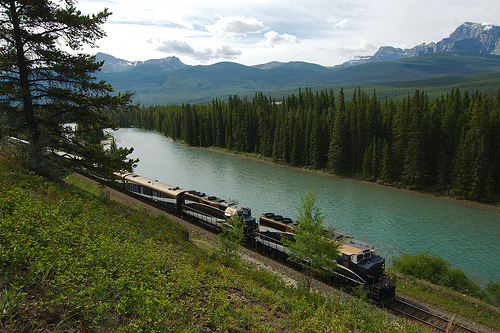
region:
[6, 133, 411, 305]
train running along a river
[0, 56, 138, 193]
pine trees overlooking a river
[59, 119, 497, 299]
light green river next to a train track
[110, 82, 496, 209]
pine trees lining the shore of a river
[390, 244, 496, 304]
green brush along the side of a river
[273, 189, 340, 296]
small tree near train tracks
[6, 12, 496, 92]
tall mountains against the sky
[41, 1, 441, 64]
bright sunlight shining off white clouds in blue sky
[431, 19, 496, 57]
rocky peak beneath blue sky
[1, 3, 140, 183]
tall pine tree above a train and a river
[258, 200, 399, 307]
the lead car of the train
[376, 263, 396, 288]
the handrail on the train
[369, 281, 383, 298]
the steps to the train platform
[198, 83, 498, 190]
the trees along the river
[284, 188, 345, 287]
the tree by the railroad tracks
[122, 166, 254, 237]
the train cars being pulled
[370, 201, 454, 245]
the ripples in the water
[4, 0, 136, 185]
the tree on the hillside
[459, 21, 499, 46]
the snow on the top of the mountain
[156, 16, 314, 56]
the clouds in the sky over the mountain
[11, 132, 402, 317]
long train on train tracks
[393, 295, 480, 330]
brown train tracks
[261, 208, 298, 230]
black port holes on top of train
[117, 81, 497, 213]
line of tall evergreen trees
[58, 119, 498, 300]
large body of blue-green water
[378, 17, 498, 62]
tall mountains in horizon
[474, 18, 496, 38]
white snow covering top of mountain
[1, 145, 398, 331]
steep grass covered hill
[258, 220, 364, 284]
white marks on side of train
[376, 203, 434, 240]
dark ripple lines in water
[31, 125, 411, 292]
train on the track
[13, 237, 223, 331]
grassy elevated land near tracks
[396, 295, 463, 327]
track train is on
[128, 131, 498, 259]
water below the train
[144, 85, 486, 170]
forest of trees across from water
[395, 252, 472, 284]
bush to side of train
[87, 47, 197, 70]
mountain in the distance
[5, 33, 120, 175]
tree above the train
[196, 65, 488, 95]
land behind the trees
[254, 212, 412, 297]
car on end of train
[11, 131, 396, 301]
A train on the tracks.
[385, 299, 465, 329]
The tracks are brown.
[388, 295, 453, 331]
Gravel around the tracks.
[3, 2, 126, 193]
A tree on the hill.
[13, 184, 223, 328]
The side of a hill.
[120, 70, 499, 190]
Evergreens line the water.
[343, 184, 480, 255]
The water is blue.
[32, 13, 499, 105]
Mountains in the distance.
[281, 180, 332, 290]
A small green tree.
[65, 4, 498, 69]
The sky is cloudy.